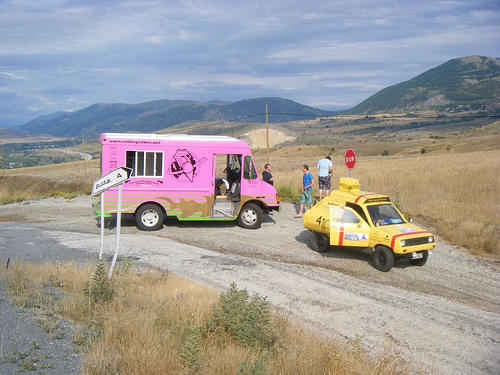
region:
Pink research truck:
[96, 129, 282, 231]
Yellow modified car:
[294, 175, 440, 272]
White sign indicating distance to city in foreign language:
[90, 163, 137, 263]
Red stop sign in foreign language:
[340, 145, 358, 175]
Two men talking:
[263, 160, 316, 216]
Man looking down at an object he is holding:
[317, 152, 335, 202]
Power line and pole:
[253, 102, 495, 159]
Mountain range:
[20, 90, 326, 131]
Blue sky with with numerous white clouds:
[13, 17, 364, 79]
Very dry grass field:
[390, 153, 498, 206]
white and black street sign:
[93, 167, 130, 293]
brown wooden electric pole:
[266, 106, 269, 166]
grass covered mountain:
[357, 53, 499, 115]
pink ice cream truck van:
[100, 133, 273, 227]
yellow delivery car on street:
[309, 176, 436, 266]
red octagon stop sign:
[344, 149, 356, 173]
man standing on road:
[299, 163, 314, 222]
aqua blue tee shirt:
[303, 172, 312, 187]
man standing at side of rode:
[318, 159, 333, 196]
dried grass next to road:
[5, 253, 416, 373]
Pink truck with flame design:
[102, 133, 284, 253]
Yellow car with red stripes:
[303, 184, 450, 299]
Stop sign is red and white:
[339, 151, 363, 188]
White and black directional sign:
[86, 165, 136, 197]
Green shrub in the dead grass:
[201, 284, 303, 371]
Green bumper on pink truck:
[91, 198, 109, 223]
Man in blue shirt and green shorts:
[298, 166, 320, 232]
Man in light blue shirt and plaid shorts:
[313, 153, 337, 203]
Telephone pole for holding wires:
[255, 102, 292, 199]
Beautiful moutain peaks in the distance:
[24, 88, 356, 145]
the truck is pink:
[90, 128, 280, 233]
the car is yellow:
[309, 173, 440, 273]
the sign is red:
[338, 146, 359, 168]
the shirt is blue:
[301, 172, 318, 190]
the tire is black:
[367, 244, 403, 273]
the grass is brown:
[139, 291, 166, 364]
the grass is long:
[116, 301, 155, 364]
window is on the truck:
[124, 147, 165, 179]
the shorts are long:
[300, 187, 312, 204]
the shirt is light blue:
[320, 155, 332, 178]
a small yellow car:
[301, 177, 434, 273]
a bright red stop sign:
[340, 150, 358, 170]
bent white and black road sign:
[88, 163, 133, 270]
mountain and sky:
[353, 42, 498, 116]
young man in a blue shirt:
[297, 162, 314, 216]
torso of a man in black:
[262, 162, 277, 184]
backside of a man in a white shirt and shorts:
[317, 153, 333, 191]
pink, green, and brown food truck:
[100, 134, 277, 230]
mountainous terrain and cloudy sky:
[0, 1, 498, 126]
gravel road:
[362, 265, 499, 370]